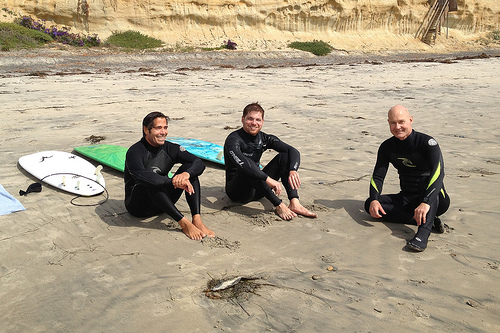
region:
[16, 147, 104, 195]
white surfboard laying on sand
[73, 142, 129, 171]
green surfboard laying on sand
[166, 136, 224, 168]
blue surfboard laying on sand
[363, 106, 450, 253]
man wearing black wetsuit sitting on sand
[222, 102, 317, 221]
man wearing black wetsuit sitting on sand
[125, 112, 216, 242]
man wearing black wetsuit sitting on sand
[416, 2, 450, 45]
wood steps leading to beach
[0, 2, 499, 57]
wall near a sandy beach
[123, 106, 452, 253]
three surfers sitting on a beach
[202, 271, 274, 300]
something washed onto a beach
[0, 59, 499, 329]
A sandy beach.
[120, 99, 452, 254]
Three men sitting on a beach.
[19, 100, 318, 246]
Three surfboards behind two men.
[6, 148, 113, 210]
White surfboard on the sand.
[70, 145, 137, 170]
Green surfboard on the beach.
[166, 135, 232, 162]
One blue surfboard on the beach.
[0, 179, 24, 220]
A blue towel on the sand.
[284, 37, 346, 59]
A patch of grass on the sand.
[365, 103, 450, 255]
A man in a wetsuit.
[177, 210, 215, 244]
A pair of feet in the sand.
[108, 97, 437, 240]
Three men sitting on the sand.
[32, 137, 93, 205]
A white surfboard on the sand.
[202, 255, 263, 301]
Seaweed in the sand.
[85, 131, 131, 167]
A green surfboard on the sand.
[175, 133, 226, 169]
A blue surfboard on the sand.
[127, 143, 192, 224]
The wetsuit is black.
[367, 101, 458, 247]
The man is wearing a black wetsuit.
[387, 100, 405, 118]
The man has a bald head.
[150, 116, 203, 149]
The man is smiling.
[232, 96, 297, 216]
The man is wet.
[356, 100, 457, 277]
man sitting on a beach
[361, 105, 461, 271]
man wearing a swim suit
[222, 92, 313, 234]
man sitting on a beach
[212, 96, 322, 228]
man wearing a swim suit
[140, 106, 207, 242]
man sitting on a beach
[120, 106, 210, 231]
man wearing a swim suit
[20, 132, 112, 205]
surf board on a beach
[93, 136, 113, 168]
surf board on a beach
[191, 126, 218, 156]
surf board on a beach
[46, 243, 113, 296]
sand on a beach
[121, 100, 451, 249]
Three men in wetsuits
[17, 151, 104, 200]
White surfboard on ground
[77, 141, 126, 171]
Green surfboard on ground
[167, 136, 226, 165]
Blue surfboard on ground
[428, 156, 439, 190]
Yellow stripe on black wetsuit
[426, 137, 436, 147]
Decal on shoulder of wetsuit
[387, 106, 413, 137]
Bald head of man in wetsuit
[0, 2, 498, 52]
Tan cliff behind beach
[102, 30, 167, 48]
Green plants at base of cliff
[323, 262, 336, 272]
Small rock on beach